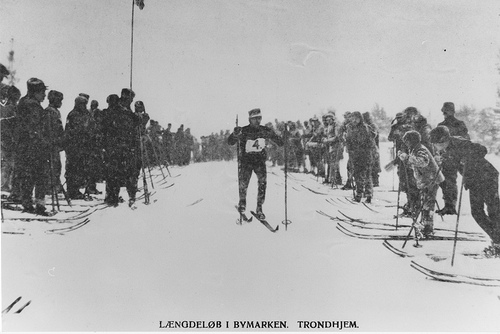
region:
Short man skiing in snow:
[228, 106, 289, 237]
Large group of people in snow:
[0, 63, 173, 238]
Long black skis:
[336, 221, 490, 246]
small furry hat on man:
[246, 106, 259, 120]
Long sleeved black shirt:
[228, 124, 283, 160]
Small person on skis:
[396, 131, 448, 240]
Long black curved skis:
[236, 203, 276, 236]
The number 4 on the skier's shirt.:
[251, 138, 259, 151]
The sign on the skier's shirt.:
[242, 139, 268, 151]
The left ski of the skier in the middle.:
[232, 202, 252, 224]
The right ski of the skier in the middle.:
[255, 205, 279, 231]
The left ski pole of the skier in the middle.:
[235, 116, 242, 221]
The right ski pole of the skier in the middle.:
[282, 121, 287, 227]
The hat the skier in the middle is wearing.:
[247, 109, 262, 118]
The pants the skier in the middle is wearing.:
[236, 162, 268, 212]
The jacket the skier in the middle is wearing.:
[229, 125, 284, 159]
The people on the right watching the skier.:
[252, 102, 496, 296]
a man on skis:
[177, 72, 304, 242]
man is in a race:
[131, 22, 360, 311]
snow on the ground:
[99, 180, 331, 300]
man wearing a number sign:
[234, 122, 280, 162]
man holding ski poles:
[208, 106, 327, 236]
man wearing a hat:
[239, 101, 263, 126]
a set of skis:
[209, 189, 295, 241]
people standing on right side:
[244, 75, 498, 307]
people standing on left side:
[5, 47, 198, 262]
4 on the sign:
[239, 130, 274, 162]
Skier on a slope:
[226, 108, 290, 234]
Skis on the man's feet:
[236, 205, 277, 233]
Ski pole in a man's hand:
[277, 122, 294, 230]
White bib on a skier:
[245, 137, 264, 152]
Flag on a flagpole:
[128, 0, 142, 90]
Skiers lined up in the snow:
[340, 103, 499, 284]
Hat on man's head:
[246, 103, 264, 118]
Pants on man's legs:
[236, 158, 264, 210]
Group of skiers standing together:
[0, 65, 158, 233]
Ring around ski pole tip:
[283, 219, 291, 226]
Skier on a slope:
[227, 108, 286, 232]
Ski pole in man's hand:
[282, 131, 290, 228]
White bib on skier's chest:
[245, 138, 264, 154]